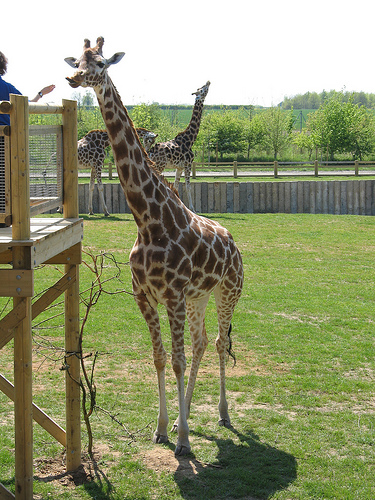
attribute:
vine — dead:
[54, 247, 127, 495]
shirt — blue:
[2, 80, 25, 126]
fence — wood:
[23, 165, 359, 177]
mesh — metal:
[27, 125, 63, 208]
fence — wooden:
[33, 177, 363, 211]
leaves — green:
[319, 107, 354, 132]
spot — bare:
[136, 443, 199, 479]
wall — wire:
[0, 125, 70, 220]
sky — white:
[4, 3, 363, 107]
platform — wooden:
[3, 88, 84, 494]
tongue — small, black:
[63, 75, 73, 84]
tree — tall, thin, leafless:
[60, 243, 135, 487]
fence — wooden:
[27, 178, 363, 216]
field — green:
[24, 108, 363, 171]